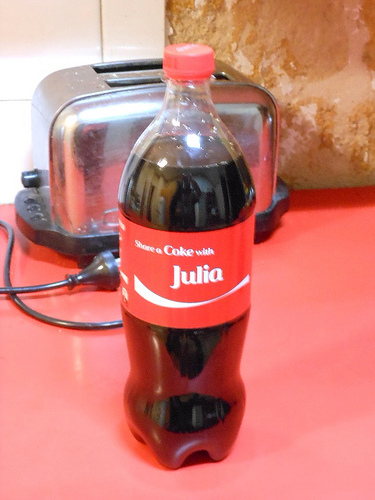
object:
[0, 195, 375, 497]
red surface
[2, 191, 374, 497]
counter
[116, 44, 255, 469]
bottle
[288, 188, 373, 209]
shadow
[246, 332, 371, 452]
shadow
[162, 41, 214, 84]
top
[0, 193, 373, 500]
table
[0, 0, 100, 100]
tiles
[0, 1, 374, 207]
wall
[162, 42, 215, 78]
bottle cap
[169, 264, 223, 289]
name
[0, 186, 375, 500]
counter top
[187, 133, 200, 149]
glare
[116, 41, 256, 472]
coke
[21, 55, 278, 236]
toaster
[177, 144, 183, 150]
drops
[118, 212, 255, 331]
label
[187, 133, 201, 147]
light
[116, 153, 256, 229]
dark liquid